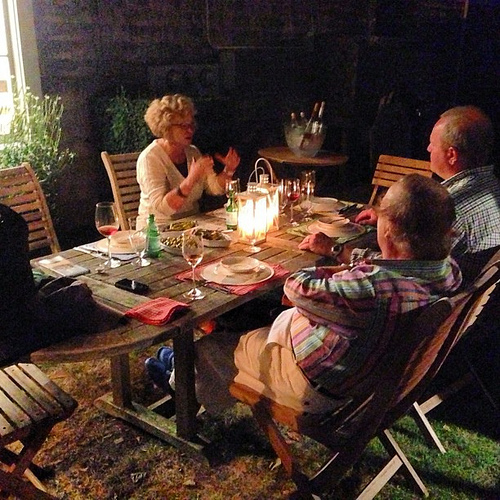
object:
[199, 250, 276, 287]
placemat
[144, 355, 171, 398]
shoe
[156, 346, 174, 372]
shoe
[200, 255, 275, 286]
plate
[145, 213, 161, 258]
glass bottle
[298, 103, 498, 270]
man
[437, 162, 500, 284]
shirt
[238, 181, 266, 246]
glass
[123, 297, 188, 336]
napkin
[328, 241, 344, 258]
watch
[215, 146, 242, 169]
hand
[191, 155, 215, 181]
hand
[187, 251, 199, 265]
wine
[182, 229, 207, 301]
glass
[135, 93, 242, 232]
people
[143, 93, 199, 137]
hair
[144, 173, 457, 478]
man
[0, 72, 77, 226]
plant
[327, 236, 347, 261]
wrist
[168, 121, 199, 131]
glasses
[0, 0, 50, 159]
window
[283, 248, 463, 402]
shirt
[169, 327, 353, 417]
pants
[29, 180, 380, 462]
table